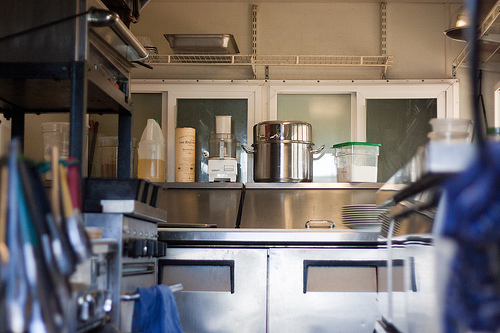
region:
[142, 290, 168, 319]
blue towel on oven handle.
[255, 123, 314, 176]
silver pot on the shelf.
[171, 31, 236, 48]
silver tray on shelf.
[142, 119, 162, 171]
liquid in plastic bottle.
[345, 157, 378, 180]
white powder in plastic container.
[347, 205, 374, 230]
stack of white plates.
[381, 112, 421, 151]
glass on cabinet door.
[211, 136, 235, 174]
mixer on the shelf.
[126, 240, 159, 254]
black knobs on appliance.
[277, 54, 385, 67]
shelving above the cabinets.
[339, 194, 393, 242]
a stack of white dishes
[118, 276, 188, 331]
a blue towel hanging by a stove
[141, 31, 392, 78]
a rack on the wall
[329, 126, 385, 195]
a plastic container with a green lid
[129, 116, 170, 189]
a plastic bottle with a liquid substance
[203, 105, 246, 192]
a food processor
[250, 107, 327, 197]
a large metal pot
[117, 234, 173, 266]
black knobs on a stove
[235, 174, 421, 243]
a lid covering food on a prep counter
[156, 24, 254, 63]
a metal track on a rack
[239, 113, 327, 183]
shiny covered pot with two handles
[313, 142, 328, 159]
shiny metal pot handle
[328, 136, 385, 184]
plastic container with green lid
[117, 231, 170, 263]
cross section of black oven knobs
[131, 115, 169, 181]
half empty container of oil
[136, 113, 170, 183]
jug of cooking oil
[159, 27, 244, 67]
shiny rectangular pan on shelf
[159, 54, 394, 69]
cross section of white metal shelving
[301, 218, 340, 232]
shiny metal handle of kitchen drawer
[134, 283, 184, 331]
blue dishcloth hanging from oven door handle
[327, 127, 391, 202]
a container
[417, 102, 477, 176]
a container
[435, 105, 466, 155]
a container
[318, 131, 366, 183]
a container